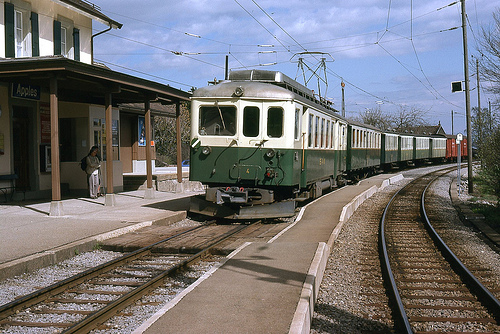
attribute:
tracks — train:
[12, 207, 205, 327]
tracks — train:
[98, 250, 176, 275]